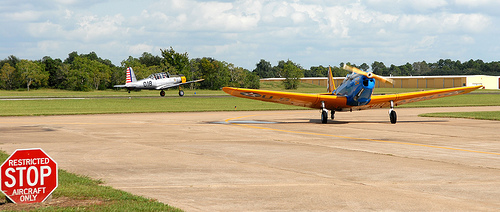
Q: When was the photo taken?
A: Day time.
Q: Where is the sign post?
A: On the left.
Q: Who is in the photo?
A: No one.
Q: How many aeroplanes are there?
A: 2.